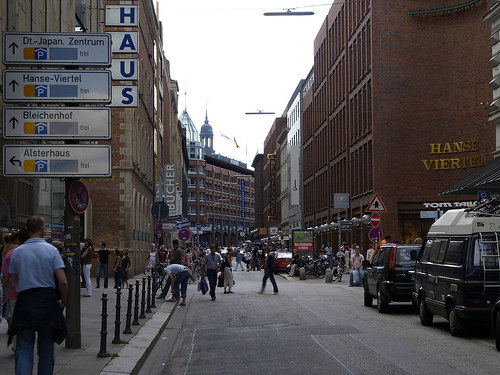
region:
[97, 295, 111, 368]
pole on the sidewalk.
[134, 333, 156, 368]
curb near the street.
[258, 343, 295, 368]
blacktop on the street.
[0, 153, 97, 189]
sign above the sidewalk.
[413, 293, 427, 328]
tire on the van.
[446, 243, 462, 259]
window on the van.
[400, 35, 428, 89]
wall made of brick.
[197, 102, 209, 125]
steeple on the dome.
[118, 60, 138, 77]
blue letter on sign.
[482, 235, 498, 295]
ladder on the van.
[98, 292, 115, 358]
post on the sidewalk.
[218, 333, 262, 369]
blacktop on the street.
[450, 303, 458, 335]
tire on the van.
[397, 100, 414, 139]
wall made of brick.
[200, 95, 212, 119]
steeple on the dome.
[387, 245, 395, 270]
tail light on jeep.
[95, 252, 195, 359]
short poles lining sidwalk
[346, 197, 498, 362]
vehicles parked in street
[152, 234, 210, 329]
man bending over tying shoe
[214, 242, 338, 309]
people crossing the street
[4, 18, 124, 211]
signs that show directions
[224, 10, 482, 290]
buildings lining a street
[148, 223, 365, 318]
a street crowded with people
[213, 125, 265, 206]
wind socks on top of building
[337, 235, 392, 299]
man holding a bag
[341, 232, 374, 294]
man holding bag sitting in a street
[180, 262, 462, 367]
street with people and vehicles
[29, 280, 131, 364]
sidewalk with people on it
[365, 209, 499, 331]
vehicles on the road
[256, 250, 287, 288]
person crossing the street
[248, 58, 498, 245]
building on the side of street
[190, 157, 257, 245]
building at end of street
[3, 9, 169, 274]
building on side of street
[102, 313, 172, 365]
curb on the sidewalk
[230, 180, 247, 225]
banner on building on end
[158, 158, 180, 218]
banner on side of building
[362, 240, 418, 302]
this is a car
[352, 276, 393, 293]
the car is black in color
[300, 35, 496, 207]
this is a building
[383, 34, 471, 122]
this is the wall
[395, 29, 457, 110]
the wall is brown in color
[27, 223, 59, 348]
this is a man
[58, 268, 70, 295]
the man is light skinned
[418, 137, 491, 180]
this is a writing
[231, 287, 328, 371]
this is the road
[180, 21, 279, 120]
this is the sky